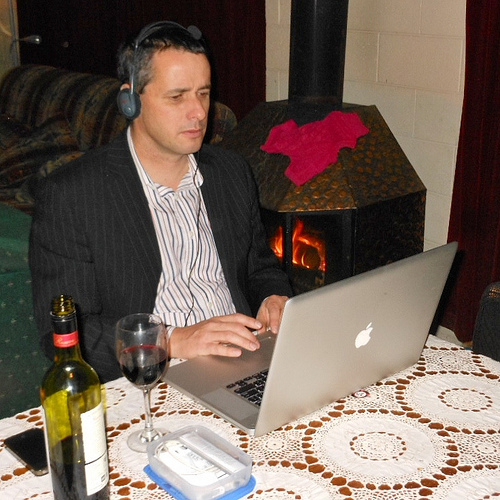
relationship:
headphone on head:
[112, 18, 207, 119] [115, 23, 217, 148]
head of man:
[115, 23, 217, 148] [24, 13, 299, 380]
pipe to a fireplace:
[287, 7, 350, 107] [234, 101, 426, 290]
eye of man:
[171, 92, 183, 99] [24, 13, 299, 380]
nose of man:
[165, 97, 218, 144] [55, 21, 297, 360]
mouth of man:
[164, 124, 205, 141] [38, 17, 364, 369]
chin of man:
[171, 137, 210, 159] [24, 13, 299, 380]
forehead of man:
[151, 50, 212, 89] [24, 13, 299, 380]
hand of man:
[169, 313, 261, 356] [24, 13, 299, 380]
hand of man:
[242, 287, 294, 352] [24, 13, 299, 380]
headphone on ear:
[112, 18, 207, 119] [116, 79, 137, 111]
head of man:
[115, 23, 217, 148] [80, 32, 268, 174]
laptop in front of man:
[155, 234, 461, 432] [14, 20, 327, 393]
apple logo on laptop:
[352, 322, 378, 350] [155, 234, 461, 432]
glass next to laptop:
[105, 316, 191, 393] [155, 234, 461, 432]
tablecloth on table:
[276, 417, 494, 497] [3, 296, 498, 498]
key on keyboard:
[234, 382, 254, 394] [223, 357, 282, 422]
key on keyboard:
[239, 378, 248, 386] [223, 357, 282, 422]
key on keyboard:
[224, 380, 235, 388] [223, 357, 282, 422]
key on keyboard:
[241, 384, 259, 397] [223, 357, 282, 422]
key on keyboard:
[253, 372, 264, 383] [223, 357, 282, 422]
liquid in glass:
[117, 342, 172, 382] [114, 311, 172, 456]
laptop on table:
[155, 234, 461, 432] [68, 219, 477, 494]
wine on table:
[45, 429, 112, 497] [4, 328, 493, 498]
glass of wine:
[114, 311, 172, 456] [116, 343, 169, 390]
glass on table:
[114, 311, 172, 456] [301, 412, 498, 497]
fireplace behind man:
[234, 101, 426, 290] [19, 20, 296, 410]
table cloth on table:
[10, 350, 496, 497] [4, 328, 493, 498]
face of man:
[154, 52, 212, 149] [55, 21, 297, 360]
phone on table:
[3, 425, 61, 480] [4, 328, 493, 498]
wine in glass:
[116, 343, 169, 390] [114, 311, 172, 456]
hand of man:
[169, 313, 261, 356] [75, 34, 289, 367]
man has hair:
[24, 13, 299, 380] [102, 26, 212, 98]